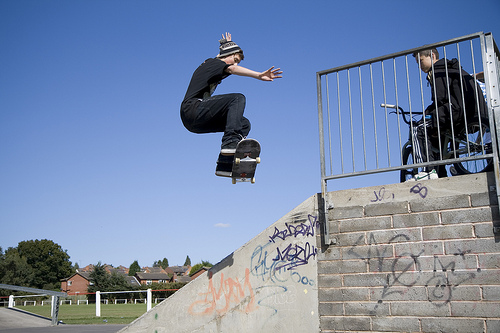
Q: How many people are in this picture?
A: Two.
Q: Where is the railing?
A: On the right.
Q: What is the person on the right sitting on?
A: A bicycle.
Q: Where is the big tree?
A: On the left.